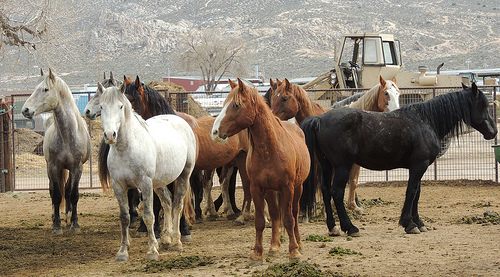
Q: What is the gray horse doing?
A: The gray horse is standing in pasture.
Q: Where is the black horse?
A: The black horse standing in pasture on the right of the other horses.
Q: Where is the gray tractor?
A: The gray tractor is on the horse farm.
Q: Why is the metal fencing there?
A: The metal gate and fencing is there to contain the horses.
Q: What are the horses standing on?
A: Dirt.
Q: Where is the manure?
A: On the ground.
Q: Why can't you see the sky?
A: Mountainous terrain.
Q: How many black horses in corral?
A: One.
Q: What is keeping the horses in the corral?
A: Fence.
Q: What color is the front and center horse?
A: Brown and white.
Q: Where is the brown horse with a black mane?
A: Behind the white horse.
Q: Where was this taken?
A: Horse corral.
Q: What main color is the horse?
A: Brown.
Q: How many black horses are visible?
A: One.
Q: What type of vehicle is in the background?
A: A tractor.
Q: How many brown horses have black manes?
A: One.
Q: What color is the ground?
A: Brown.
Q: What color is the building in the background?
A: Red.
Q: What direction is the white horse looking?
A: To the left.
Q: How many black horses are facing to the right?
A: One.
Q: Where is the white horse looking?
A: At the camera.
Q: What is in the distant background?
A: Mountains.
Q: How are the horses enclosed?
A: Fence.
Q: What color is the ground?
A: Brown and green.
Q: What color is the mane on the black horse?
A: Black.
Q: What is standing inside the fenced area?
A: Horses.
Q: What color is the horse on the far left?
A: Grey.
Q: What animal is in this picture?
A: Horses.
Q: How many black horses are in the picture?
A: One.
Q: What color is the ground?
A: Brown.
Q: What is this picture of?
A: Horses.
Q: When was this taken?
A: Daytime.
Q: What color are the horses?
A: Black, brown, white, grey.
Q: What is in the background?
A: Hills.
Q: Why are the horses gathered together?
A: They're fenced in.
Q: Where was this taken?
A: A horse farm.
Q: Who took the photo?
A: A photographer.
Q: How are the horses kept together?
A: A fence.